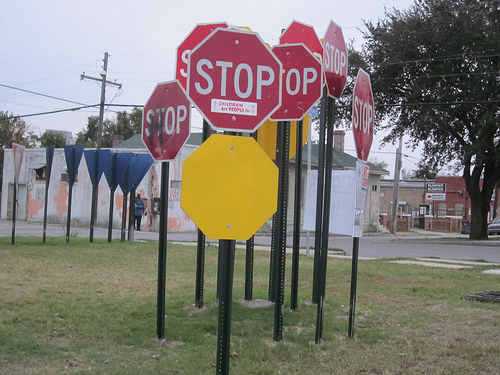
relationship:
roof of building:
[114, 129, 387, 173] [120, 129, 392, 237]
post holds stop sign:
[154, 160, 172, 339] [141, 80, 193, 161]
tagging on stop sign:
[150, 110, 164, 145] [141, 80, 193, 161]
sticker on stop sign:
[210, 98, 258, 118] [186, 26, 283, 136]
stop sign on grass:
[141, 80, 193, 161] [1, 237, 499, 375]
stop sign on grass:
[186, 26, 283, 136] [1, 237, 499, 375]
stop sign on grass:
[268, 43, 324, 123] [1, 237, 499, 375]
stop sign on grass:
[321, 19, 350, 100] [1, 237, 499, 375]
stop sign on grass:
[351, 67, 378, 161] [1, 237, 499, 375]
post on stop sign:
[154, 160, 172, 339] [141, 80, 193, 161]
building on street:
[1, 148, 195, 232] [1, 217, 500, 267]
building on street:
[120, 129, 392, 237] [1, 217, 500, 267]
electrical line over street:
[0, 104, 101, 121] [1, 217, 500, 267]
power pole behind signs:
[81, 51, 122, 223] [28, 118, 175, 205]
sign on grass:
[180, 133, 280, 239] [1, 237, 499, 375]